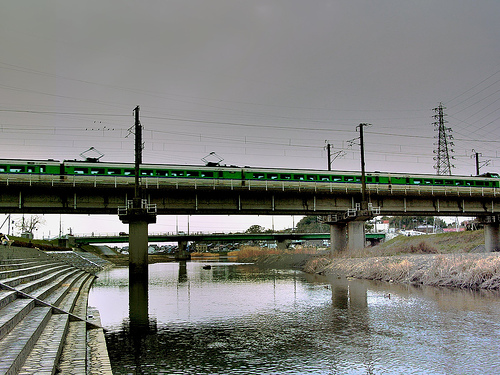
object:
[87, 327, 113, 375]
concrete step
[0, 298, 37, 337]
concrete step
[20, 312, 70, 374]
concrete step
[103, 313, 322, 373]
reflection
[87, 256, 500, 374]
water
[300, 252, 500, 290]
grass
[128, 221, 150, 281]
pier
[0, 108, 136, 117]
wiring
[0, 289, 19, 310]
steps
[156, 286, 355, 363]
water body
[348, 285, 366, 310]
reflections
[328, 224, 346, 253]
columns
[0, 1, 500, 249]
sky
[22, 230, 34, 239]
structure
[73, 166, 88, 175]
rectangular windows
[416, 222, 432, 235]
buildings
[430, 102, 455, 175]
tower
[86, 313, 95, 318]
stone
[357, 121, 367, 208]
light pole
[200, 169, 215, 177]
window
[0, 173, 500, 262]
bridges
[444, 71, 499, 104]
wires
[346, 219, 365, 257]
pier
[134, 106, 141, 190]
poles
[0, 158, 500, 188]
train